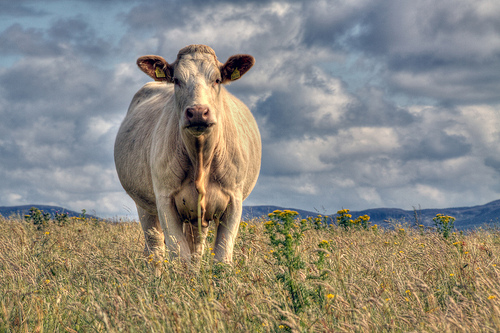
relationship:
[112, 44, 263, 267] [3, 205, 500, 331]
cow in field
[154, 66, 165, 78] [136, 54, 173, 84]
tag in ear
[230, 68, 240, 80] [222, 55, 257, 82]
tag in ear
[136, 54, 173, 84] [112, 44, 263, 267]
ear on cow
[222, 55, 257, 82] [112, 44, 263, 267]
ear on cow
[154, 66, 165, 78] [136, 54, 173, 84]
tag on ear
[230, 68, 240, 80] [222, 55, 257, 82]
tag on ear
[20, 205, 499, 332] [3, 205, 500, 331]
flowers in field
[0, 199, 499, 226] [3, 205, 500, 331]
hill behind field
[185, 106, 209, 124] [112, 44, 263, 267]
nose on cow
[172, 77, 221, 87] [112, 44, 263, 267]
eyes on cow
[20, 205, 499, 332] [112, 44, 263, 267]
flowers near cow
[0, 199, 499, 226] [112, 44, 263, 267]
hill behind cow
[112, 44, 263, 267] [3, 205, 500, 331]
cow standing in field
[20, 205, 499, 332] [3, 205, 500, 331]
flowers growing in field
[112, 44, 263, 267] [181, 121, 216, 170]
cow has a neck